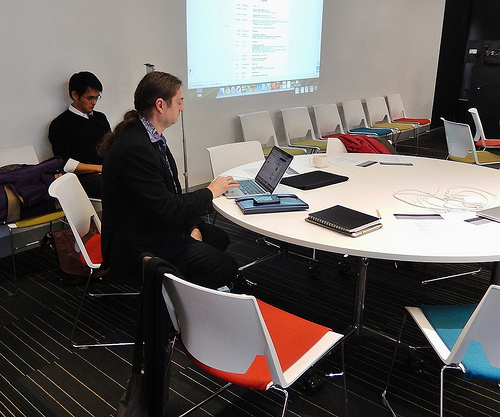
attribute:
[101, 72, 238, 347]
man — sitting, well dressed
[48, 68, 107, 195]
man — sitting, young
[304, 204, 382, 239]
notebooks — piled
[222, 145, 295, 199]
laptop — silver, here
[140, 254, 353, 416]
chair — blue, orange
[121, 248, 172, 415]
bag — hanging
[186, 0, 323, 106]
projection — business related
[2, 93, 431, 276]
chairs — empty, white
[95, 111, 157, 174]
pony tail — brown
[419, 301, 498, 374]
seat — blue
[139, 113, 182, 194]
shirt — lavender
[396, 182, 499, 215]
cable — white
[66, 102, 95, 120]
shirt — white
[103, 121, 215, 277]
jacket — black